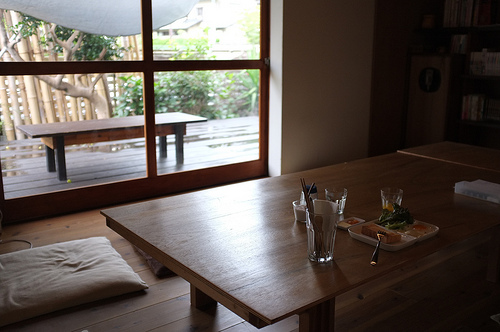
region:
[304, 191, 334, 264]
a glass with utensils in it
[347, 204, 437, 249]
food inside of a tray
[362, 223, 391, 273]
a fork leaning on the tray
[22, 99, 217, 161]
a bench on the porch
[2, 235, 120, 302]
a floor pillow for sitting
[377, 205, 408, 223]
some green vegetables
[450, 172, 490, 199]
some napkins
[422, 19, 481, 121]
bookshelves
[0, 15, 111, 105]
a bonsai tree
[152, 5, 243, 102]
the backyard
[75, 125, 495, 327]
A wooden table is in the foreground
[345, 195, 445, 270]
A white tray with food in it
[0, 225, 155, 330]
A pillow is on the floor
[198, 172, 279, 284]
Light is reflecting off the table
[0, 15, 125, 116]
A tree is in the background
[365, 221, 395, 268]
A silver fork is on the table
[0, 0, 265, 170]
A window is in the background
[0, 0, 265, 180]
A window is in a wooden frame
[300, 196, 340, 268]
A glass cup is on the table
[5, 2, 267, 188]
Photo was taken in the daytime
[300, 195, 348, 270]
glass on a table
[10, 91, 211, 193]
wooden bench on a porch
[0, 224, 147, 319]
pillow lying on the ground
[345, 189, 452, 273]
a plate of food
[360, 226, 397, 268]
a silver metal fork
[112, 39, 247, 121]
bush with green leaves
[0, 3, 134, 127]
a tree growing outside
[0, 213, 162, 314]
tan pillow on the floor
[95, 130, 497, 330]
wooden table with food on it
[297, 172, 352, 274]
glass with chopsticks inside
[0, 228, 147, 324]
An off white pillow on a wood floor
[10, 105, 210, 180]
A brown wood bench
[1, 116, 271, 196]
A wet porch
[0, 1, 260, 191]
A view through a window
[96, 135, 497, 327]
A wood Japanese table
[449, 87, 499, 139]
Books on a shelf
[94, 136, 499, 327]
A table with short legs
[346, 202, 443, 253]
A white plate with compartments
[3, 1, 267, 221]
A window with a wood frame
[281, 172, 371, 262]
Chopsticks in a glass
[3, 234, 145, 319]
cream-colored mat on floor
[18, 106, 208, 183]
wooden bench outside window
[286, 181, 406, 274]
glasses on wooden table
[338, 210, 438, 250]
meal on TV dinner tray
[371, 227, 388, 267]
fork hanging off TV dinner tray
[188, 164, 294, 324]
sunlight shines on wooden table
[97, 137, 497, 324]
light brown wooden table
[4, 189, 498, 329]
brown hardwood floor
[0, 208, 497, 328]
long lines on floor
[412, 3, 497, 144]
wooden bookcase in background